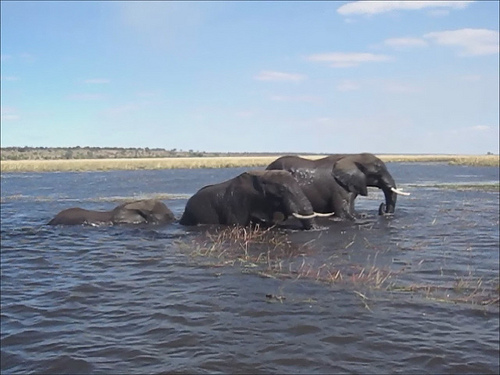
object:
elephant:
[175, 167, 337, 230]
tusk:
[291, 209, 323, 221]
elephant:
[194, 130, 419, 249]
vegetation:
[4, 156, 499, 171]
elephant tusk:
[386, 187, 409, 197]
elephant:
[182, 173, 335, 233]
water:
[1, 163, 500, 373]